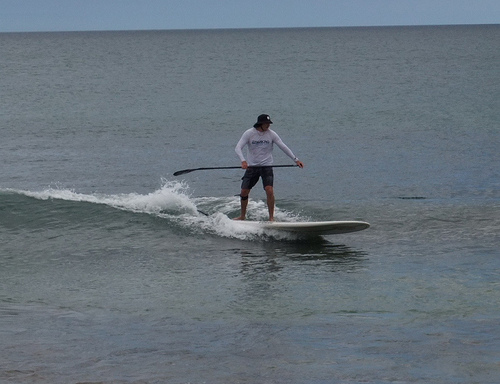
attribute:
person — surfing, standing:
[221, 110, 307, 219]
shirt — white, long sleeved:
[232, 126, 296, 177]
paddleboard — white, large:
[213, 206, 382, 245]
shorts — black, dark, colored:
[235, 165, 282, 193]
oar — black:
[171, 159, 310, 182]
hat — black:
[251, 110, 276, 127]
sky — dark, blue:
[0, 0, 499, 37]